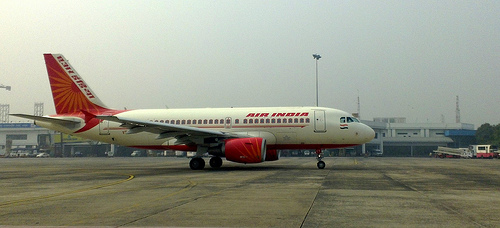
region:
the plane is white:
[19, 48, 405, 196]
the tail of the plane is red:
[5, 45, 116, 130]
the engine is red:
[218, 127, 275, 180]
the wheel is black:
[295, 147, 336, 170]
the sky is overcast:
[115, 10, 482, 115]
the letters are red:
[233, 95, 316, 125]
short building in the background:
[87, 102, 229, 142]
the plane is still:
[10, 50, 400, 196]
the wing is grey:
[85, 107, 238, 142]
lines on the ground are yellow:
[40, 156, 182, 207]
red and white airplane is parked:
[7, 53, 374, 170]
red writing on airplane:
[245, 112, 312, 117]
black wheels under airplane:
[189, 154, 325, 171]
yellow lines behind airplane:
[0, 170, 197, 226]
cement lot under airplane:
[0, 155, 498, 226]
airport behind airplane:
[0, 120, 476, 157]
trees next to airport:
[475, 121, 499, 147]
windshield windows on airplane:
[339, 116, 359, 121]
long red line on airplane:
[101, 124, 304, 130]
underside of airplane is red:
[124, 141, 360, 150]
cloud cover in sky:
[1, 2, 498, 124]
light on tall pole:
[311, 53, 322, 107]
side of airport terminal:
[368, 120, 476, 157]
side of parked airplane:
[15, 52, 375, 169]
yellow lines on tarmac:
[1, 169, 196, 226]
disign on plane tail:
[43, 51, 105, 128]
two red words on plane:
[245, 110, 310, 120]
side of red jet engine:
[224, 136, 266, 163]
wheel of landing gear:
[313, 151, 328, 170]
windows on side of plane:
[163, 115, 313, 125]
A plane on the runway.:
[41, 52, 376, 176]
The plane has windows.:
[199, 110, 306, 132]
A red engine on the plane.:
[223, 132, 267, 166]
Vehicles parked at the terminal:
[435, 134, 499, 165]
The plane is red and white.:
[43, 66, 377, 172]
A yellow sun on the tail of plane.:
[54, 73, 79, 111]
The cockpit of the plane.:
[336, 104, 367, 134]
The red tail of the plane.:
[26, 41, 113, 109]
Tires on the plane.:
[177, 142, 232, 177]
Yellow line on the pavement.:
[21, 153, 166, 205]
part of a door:
[313, 105, 321, 131]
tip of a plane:
[370, 126, 375, 134]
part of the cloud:
[261, 40, 271, 55]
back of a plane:
[91, 74, 109, 113]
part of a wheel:
[318, 161, 323, 166]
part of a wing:
[243, 140, 248, 147]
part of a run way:
[283, 198, 292, 213]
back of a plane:
[77, 87, 87, 100]